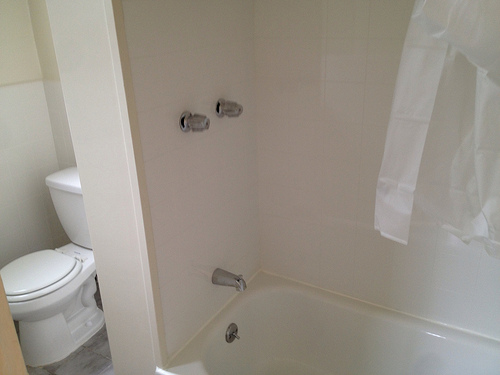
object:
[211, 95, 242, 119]
knob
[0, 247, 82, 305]
seat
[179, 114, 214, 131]
knob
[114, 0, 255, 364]
wall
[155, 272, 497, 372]
tub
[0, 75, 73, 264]
tile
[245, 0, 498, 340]
wall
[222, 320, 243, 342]
stopper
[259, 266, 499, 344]
rim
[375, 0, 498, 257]
curtain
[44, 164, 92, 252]
tank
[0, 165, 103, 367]
toilet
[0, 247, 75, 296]
cover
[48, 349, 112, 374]
tile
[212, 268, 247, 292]
faucet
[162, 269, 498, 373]
bath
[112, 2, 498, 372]
shower